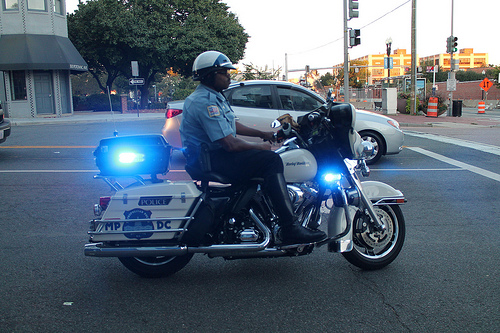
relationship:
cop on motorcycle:
[179, 51, 324, 246] [85, 92, 408, 277]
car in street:
[164, 76, 404, 164] [3, 126, 499, 332]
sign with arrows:
[479, 74, 494, 94] [481, 81, 492, 90]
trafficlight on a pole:
[446, 35, 461, 55] [450, 112, 455, 114]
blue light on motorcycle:
[105, 145, 147, 170] [85, 92, 408, 277]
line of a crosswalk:
[409, 128, 499, 157] [404, 115, 500, 156]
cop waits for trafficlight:
[179, 51, 324, 246] [446, 35, 461, 55]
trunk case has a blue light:
[92, 135, 174, 176] [105, 145, 147, 170]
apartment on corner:
[1, 2, 89, 115] [341, 43, 435, 131]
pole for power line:
[409, 3, 418, 114] [353, 0, 410, 34]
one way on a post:
[126, 76, 148, 87] [133, 84, 143, 119]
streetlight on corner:
[383, 37, 397, 112] [341, 43, 435, 131]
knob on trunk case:
[111, 128, 121, 141] [92, 135, 174, 176]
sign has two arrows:
[479, 74, 494, 94] [481, 81, 492, 90]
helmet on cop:
[193, 46, 236, 71] [179, 51, 324, 246]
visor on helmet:
[222, 63, 240, 71] [193, 46, 236, 71]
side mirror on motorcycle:
[269, 116, 291, 133] [85, 92, 408, 277]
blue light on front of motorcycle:
[317, 167, 349, 189] [85, 92, 408, 277]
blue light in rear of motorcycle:
[105, 145, 147, 170] [85, 92, 408, 277]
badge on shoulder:
[209, 102, 221, 122] [185, 84, 228, 140]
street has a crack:
[3, 126, 499, 332] [362, 265, 407, 330]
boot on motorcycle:
[257, 173, 324, 244] [85, 92, 408, 277]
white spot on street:
[61, 298, 75, 308] [3, 126, 499, 332]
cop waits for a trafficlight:
[179, 51, 324, 246] [446, 35, 461, 55]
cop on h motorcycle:
[179, 51, 324, 246] [85, 92, 408, 277]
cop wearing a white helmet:
[179, 51, 324, 246] [193, 46, 236, 71]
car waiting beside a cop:
[164, 76, 404, 164] [179, 51, 324, 246]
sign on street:
[479, 74, 494, 94] [1, 122, 499, 278]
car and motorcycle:
[164, 76, 404, 164] [85, 92, 408, 277]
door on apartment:
[33, 72, 56, 114] [1, 2, 89, 115]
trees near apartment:
[68, 2, 247, 113] [1, 2, 89, 115]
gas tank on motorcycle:
[275, 141, 319, 184] [85, 92, 408, 277]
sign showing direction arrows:
[479, 74, 494, 94] [481, 81, 492, 90]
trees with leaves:
[68, 2, 247, 113] [65, 2, 247, 59]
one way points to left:
[126, 76, 148, 87] [3, 2, 96, 332]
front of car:
[357, 94, 405, 163] [164, 76, 404, 164]